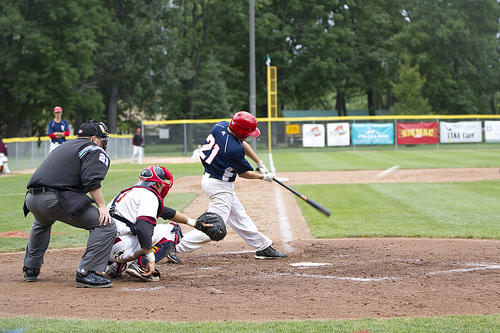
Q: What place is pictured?
A: It is a field.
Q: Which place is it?
A: It is a field.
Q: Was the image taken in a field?
A: Yes, it was taken in a field.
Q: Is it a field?
A: Yes, it is a field.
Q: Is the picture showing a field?
A: Yes, it is showing a field.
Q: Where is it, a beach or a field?
A: It is a field.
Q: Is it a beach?
A: No, it is a field.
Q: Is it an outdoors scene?
A: Yes, it is outdoors.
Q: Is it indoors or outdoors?
A: It is outdoors.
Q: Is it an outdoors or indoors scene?
A: It is outdoors.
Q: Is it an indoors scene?
A: No, it is outdoors.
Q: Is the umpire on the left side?
A: Yes, the umpire is on the left of the image.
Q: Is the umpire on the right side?
A: No, the umpire is on the left of the image.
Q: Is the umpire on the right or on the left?
A: The umpire is on the left of the image.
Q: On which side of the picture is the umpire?
A: The umpire is on the left of the image.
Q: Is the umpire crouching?
A: Yes, the umpire is crouching.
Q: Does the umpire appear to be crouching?
A: Yes, the umpire is crouching.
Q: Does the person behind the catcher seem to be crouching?
A: Yes, the umpire is crouching.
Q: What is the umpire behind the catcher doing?
A: The umpire is crouching.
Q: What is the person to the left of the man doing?
A: The umpire is crouching.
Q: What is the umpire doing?
A: The umpire is crouching.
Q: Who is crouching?
A: The umpire is crouching.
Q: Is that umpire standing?
A: No, the umpire is crouching.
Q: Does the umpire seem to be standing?
A: No, the umpire is crouching.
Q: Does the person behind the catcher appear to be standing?
A: No, the umpire is crouching.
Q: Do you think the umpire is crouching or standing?
A: The umpire is crouching.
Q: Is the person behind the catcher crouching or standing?
A: The umpire is crouching.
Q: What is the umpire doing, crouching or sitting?
A: The umpire is crouching.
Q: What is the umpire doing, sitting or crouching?
A: The umpire is crouching.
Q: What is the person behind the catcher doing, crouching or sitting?
A: The umpire is crouching.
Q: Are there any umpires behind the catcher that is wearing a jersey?
A: Yes, there is an umpire behind the catcher.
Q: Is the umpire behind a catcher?
A: Yes, the umpire is behind a catcher.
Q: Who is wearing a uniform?
A: The umpire is wearing a uniform.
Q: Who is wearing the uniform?
A: The umpire is wearing a uniform.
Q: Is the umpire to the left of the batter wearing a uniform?
A: Yes, the umpire is wearing a uniform.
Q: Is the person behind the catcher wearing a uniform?
A: Yes, the umpire is wearing a uniform.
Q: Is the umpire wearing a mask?
A: No, the umpire is wearing a uniform.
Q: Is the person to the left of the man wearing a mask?
A: No, the umpire is wearing a uniform.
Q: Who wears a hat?
A: The umpire wears a hat.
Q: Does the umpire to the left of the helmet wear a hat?
A: Yes, the umpire wears a hat.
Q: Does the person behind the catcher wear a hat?
A: Yes, the umpire wears a hat.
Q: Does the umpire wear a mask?
A: No, the umpire wears a hat.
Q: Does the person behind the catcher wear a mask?
A: No, the umpire wears a hat.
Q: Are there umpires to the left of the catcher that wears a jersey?
A: Yes, there is an umpire to the left of the catcher.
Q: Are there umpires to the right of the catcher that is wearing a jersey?
A: No, the umpire is to the left of the catcher.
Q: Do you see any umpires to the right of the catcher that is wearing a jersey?
A: No, the umpire is to the left of the catcher.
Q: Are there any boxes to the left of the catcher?
A: No, there is an umpire to the left of the catcher.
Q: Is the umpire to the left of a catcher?
A: Yes, the umpire is to the left of a catcher.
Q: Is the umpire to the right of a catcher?
A: No, the umpire is to the left of a catcher.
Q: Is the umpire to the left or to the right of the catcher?
A: The umpire is to the left of the catcher.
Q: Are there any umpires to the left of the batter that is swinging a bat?
A: Yes, there is an umpire to the left of the batter.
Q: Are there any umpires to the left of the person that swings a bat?
A: Yes, there is an umpire to the left of the batter.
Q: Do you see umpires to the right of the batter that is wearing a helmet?
A: No, the umpire is to the left of the batter.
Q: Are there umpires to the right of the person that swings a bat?
A: No, the umpire is to the left of the batter.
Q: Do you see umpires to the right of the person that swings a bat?
A: No, the umpire is to the left of the batter.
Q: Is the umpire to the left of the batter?
A: Yes, the umpire is to the left of the batter.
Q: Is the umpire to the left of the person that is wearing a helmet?
A: Yes, the umpire is to the left of the batter.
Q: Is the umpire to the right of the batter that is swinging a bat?
A: No, the umpire is to the left of the batter.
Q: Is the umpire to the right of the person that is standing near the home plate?
A: No, the umpire is to the left of the batter.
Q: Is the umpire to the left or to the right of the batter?
A: The umpire is to the left of the batter.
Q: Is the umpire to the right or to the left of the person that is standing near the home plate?
A: The umpire is to the left of the batter.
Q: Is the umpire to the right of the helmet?
A: No, the umpire is to the left of the helmet.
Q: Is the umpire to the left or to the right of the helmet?
A: The umpire is to the left of the helmet.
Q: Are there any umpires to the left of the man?
A: Yes, there is an umpire to the left of the man.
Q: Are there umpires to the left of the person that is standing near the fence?
A: Yes, there is an umpire to the left of the man.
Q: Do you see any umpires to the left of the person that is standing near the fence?
A: Yes, there is an umpire to the left of the man.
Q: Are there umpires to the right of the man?
A: No, the umpire is to the left of the man.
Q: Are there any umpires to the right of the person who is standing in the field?
A: No, the umpire is to the left of the man.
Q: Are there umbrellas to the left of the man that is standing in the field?
A: No, there is an umpire to the left of the man.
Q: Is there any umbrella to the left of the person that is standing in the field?
A: No, there is an umpire to the left of the man.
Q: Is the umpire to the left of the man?
A: Yes, the umpire is to the left of the man.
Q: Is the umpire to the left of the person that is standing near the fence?
A: Yes, the umpire is to the left of the man.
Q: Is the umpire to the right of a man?
A: No, the umpire is to the left of a man.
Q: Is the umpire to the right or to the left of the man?
A: The umpire is to the left of the man.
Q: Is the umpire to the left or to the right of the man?
A: The umpire is to the left of the man.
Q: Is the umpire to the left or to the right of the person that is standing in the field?
A: The umpire is to the left of the man.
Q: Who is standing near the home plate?
A: The batter is standing near the home plate.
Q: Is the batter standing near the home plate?
A: Yes, the batter is standing near the home plate.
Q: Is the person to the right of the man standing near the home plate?
A: Yes, the batter is standing near the home plate.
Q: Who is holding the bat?
A: The batter is holding the bat.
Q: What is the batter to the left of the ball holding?
A: The batter is holding the bat.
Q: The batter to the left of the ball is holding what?
A: The batter is holding the bat.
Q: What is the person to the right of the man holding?
A: The batter is holding the bat.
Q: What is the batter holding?
A: The batter is holding the bat.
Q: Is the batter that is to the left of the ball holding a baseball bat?
A: No, the batter is holding the bat.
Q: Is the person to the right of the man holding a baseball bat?
A: No, the batter is holding the bat.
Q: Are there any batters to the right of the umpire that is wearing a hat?
A: Yes, there is a batter to the right of the umpire.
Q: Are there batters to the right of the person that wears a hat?
A: Yes, there is a batter to the right of the umpire.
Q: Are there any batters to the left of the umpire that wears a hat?
A: No, the batter is to the right of the umpire.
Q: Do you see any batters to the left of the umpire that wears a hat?
A: No, the batter is to the right of the umpire.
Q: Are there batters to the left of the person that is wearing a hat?
A: No, the batter is to the right of the umpire.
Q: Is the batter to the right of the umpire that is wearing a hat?
A: Yes, the batter is to the right of the umpire.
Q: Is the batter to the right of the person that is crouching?
A: Yes, the batter is to the right of the umpire.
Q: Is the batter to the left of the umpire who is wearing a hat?
A: No, the batter is to the right of the umpire.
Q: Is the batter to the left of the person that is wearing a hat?
A: No, the batter is to the right of the umpire.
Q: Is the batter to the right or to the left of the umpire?
A: The batter is to the right of the umpire.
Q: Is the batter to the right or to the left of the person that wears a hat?
A: The batter is to the right of the umpire.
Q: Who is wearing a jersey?
A: The batter is wearing a jersey.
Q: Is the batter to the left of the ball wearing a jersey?
A: Yes, the batter is wearing a jersey.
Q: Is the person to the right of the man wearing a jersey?
A: Yes, the batter is wearing a jersey.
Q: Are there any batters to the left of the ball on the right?
A: Yes, there is a batter to the left of the ball.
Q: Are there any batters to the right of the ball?
A: No, the batter is to the left of the ball.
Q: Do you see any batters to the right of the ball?
A: No, the batter is to the left of the ball.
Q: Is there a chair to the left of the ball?
A: No, there is a batter to the left of the ball.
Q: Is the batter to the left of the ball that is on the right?
A: Yes, the batter is to the left of the ball.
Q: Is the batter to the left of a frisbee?
A: No, the batter is to the left of the ball.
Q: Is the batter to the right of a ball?
A: No, the batter is to the left of a ball.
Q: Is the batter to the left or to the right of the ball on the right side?
A: The batter is to the left of the ball.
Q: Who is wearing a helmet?
A: The batter is wearing a helmet.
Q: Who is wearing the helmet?
A: The batter is wearing a helmet.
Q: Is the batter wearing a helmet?
A: Yes, the batter is wearing a helmet.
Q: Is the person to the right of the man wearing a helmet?
A: Yes, the batter is wearing a helmet.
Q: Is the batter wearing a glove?
A: No, the batter is wearing a helmet.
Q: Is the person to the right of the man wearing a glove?
A: No, the batter is wearing a helmet.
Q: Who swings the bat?
A: The batter swings the bat.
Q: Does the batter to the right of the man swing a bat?
A: Yes, the batter swings a bat.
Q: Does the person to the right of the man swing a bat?
A: Yes, the batter swings a bat.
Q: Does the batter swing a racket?
A: No, the batter swings a bat.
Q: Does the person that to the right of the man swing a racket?
A: No, the batter swings a bat.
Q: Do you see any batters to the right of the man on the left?
A: Yes, there is a batter to the right of the man.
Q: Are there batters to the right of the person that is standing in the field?
A: Yes, there is a batter to the right of the man.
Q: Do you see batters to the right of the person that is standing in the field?
A: Yes, there is a batter to the right of the man.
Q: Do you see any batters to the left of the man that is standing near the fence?
A: No, the batter is to the right of the man.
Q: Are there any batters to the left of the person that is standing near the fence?
A: No, the batter is to the right of the man.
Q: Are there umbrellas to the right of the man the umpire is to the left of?
A: No, there is a batter to the right of the man.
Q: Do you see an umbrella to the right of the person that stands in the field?
A: No, there is a batter to the right of the man.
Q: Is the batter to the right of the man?
A: Yes, the batter is to the right of the man.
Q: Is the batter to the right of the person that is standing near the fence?
A: Yes, the batter is to the right of the man.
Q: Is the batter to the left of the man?
A: No, the batter is to the right of the man.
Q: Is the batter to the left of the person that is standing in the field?
A: No, the batter is to the right of the man.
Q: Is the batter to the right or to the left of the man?
A: The batter is to the right of the man.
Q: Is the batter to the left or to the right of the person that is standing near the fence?
A: The batter is to the right of the man.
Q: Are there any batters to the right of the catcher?
A: Yes, there is a batter to the right of the catcher.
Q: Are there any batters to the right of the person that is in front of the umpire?
A: Yes, there is a batter to the right of the catcher.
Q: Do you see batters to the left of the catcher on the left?
A: No, the batter is to the right of the catcher.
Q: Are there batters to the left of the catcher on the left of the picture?
A: No, the batter is to the right of the catcher.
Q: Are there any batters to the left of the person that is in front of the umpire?
A: No, the batter is to the right of the catcher.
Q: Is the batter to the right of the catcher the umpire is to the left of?
A: Yes, the batter is to the right of the catcher.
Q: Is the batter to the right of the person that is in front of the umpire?
A: Yes, the batter is to the right of the catcher.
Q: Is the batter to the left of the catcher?
A: No, the batter is to the right of the catcher.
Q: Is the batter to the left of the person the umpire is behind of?
A: No, the batter is to the right of the catcher.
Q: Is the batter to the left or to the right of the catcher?
A: The batter is to the right of the catcher.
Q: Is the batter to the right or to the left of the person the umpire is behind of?
A: The batter is to the right of the catcher.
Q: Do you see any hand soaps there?
A: No, there are no hand soaps.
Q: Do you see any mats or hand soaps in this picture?
A: No, there are no hand soaps or mats.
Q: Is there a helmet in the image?
A: Yes, there is a helmet.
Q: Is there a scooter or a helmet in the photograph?
A: Yes, there is a helmet.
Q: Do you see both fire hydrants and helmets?
A: No, there is a helmet but no fire hydrants.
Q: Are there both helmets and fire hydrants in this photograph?
A: No, there is a helmet but no fire hydrants.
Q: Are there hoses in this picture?
A: No, there are no hoses.